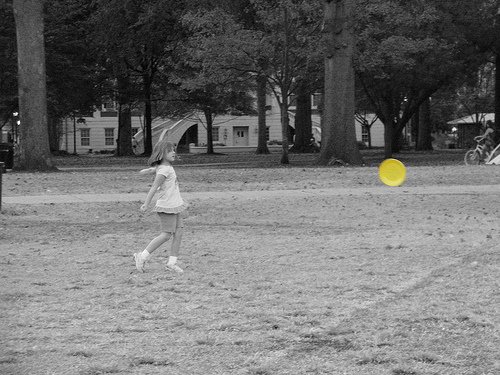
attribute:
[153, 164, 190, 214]
shirt — light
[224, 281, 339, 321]
grass — clumpy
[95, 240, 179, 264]
shoes — white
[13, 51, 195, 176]
building — white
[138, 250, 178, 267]
socks — white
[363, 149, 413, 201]
flying disc — yellow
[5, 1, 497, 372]
picture — black, white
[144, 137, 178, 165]
hair — dark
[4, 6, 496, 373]
photo — black, white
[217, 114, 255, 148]
doors — double, white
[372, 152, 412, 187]
disc — yellow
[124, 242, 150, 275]
shoes — light colored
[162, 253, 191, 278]
shoes — light colored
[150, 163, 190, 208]
shirt — light colored